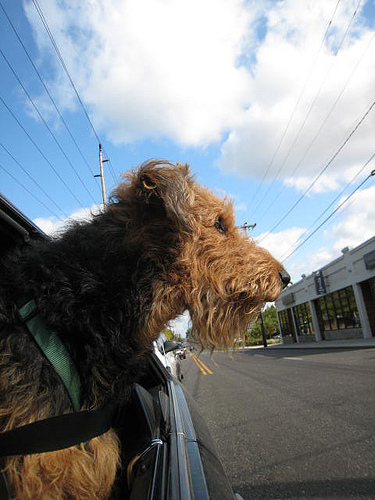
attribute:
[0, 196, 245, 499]
car — black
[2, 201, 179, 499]
window — down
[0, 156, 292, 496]
dog — light brown, facing right, curious, brown, friendly, nosy, very curious, interested, hairy, nice, staring, cute, adorable, terrier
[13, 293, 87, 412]
collar — green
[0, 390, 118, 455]
safety belt — black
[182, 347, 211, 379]
lines — yellow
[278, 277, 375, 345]
windows — glass, large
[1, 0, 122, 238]
power lines — high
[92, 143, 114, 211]
pole — wood, wooden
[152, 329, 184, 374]
car — white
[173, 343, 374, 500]
street — paved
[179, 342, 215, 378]
divider — yellow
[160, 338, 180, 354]
rear view mirror — black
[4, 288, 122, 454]
restraints — canvas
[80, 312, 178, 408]
fur — black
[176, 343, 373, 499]
roadway — cement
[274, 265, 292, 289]
nose — black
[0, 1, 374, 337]
sky — full of clouds, blue, cloudy, beautiful